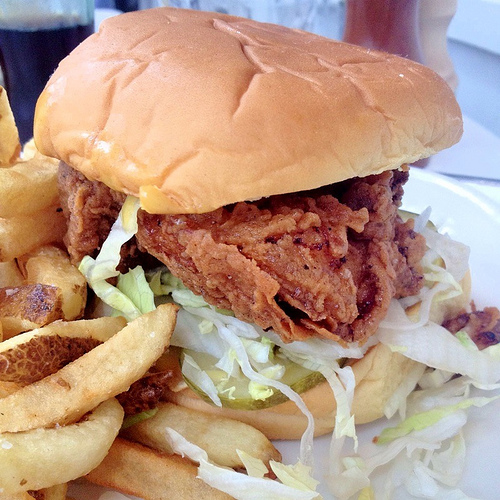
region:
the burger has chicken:
[69, 127, 426, 482]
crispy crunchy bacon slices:
[176, 220, 384, 316]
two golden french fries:
[117, 407, 286, 494]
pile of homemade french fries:
[8, 317, 260, 498]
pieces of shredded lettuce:
[307, 423, 462, 484]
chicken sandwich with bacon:
[38, 12, 454, 425]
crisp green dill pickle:
[182, 342, 318, 407]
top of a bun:
[39, 15, 461, 190]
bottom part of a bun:
[179, 384, 450, 421]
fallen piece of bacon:
[446, 300, 492, 380]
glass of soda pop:
[4, 0, 91, 139]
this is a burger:
[56, 23, 458, 435]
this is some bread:
[136, 37, 289, 124]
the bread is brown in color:
[162, 25, 243, 120]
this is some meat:
[188, 221, 407, 324]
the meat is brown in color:
[279, 210, 371, 312]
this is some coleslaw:
[239, 351, 477, 483]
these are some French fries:
[6, 167, 246, 485]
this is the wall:
[462, 3, 487, 41]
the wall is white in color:
[461, 6, 495, 48]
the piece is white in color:
[411, 327, 445, 362]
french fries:
[1, 335, 186, 484]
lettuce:
[344, 433, 469, 496]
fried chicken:
[152, 215, 420, 317]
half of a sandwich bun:
[14, 15, 470, 191]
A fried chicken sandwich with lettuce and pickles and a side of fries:
[5, 3, 481, 494]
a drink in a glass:
[0, 3, 96, 143]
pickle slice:
[181, 354, 323, 400]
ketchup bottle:
[349, 8, 419, 53]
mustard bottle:
[419, 1, 466, 65]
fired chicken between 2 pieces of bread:
[79, 26, 473, 425]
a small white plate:
[35, 123, 497, 498]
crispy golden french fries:
[1, 103, 267, 496]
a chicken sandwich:
[33, 5, 488, 449]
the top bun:
[23, 5, 483, 230]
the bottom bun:
[165, 288, 464, 433]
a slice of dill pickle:
[182, 338, 344, 415]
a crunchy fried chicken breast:
[81, 200, 412, 317]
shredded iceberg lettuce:
[298, 431, 464, 492]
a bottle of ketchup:
[340, 1, 436, 168]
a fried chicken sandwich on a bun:
[20, 5, 489, 455]